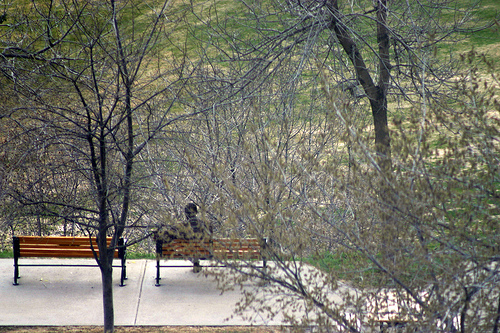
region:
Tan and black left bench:
[10, 229, 127, 279]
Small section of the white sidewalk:
[158, 290, 210, 320]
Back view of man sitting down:
[163, 202, 209, 239]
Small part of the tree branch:
[46, 198, 59, 208]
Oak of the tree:
[102, 302, 122, 322]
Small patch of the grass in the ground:
[236, 20, 242, 30]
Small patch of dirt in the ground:
[133, 327, 148, 332]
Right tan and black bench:
[158, 238, 272, 288]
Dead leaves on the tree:
[228, 310, 250, 324]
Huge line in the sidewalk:
[126, 259, 159, 324]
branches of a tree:
[420, 166, 455, 196]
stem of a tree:
[107, 291, 112, 306]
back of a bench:
[51, 220, 74, 250]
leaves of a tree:
[373, 213, 411, 262]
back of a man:
[181, 198, 193, 220]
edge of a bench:
[42, 223, 67, 256]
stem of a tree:
[385, 175, 425, 267]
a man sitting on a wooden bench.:
[127, 169, 304, 322]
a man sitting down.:
[176, 199, 220, 273]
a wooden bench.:
[0, 217, 144, 296]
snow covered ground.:
[0, 251, 499, 321]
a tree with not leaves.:
[63, 1, 126, 329]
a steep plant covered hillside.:
[3, 0, 498, 259]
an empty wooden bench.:
[0, 223, 137, 288]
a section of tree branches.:
[123, 59, 204, 146]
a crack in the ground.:
[131, 259, 154, 324]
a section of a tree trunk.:
[297, 50, 417, 127]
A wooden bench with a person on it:
[136, 187, 286, 289]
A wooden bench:
[2, 212, 144, 300]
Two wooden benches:
[8, 182, 293, 304]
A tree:
[250, 7, 461, 315]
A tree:
[15, 5, 204, 330]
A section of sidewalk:
[118, 289, 185, 325]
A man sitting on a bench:
[163, 186, 220, 281]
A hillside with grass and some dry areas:
[152, 5, 252, 63]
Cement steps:
[301, 255, 377, 330]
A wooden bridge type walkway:
[358, 269, 498, 331]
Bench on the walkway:
[7, 225, 139, 295]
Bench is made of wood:
[1, 228, 136, 297]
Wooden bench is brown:
[10, 230, 133, 287]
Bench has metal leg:
[6, 232, 29, 296]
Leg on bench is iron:
[5, 230, 32, 289]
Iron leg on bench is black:
[5, 230, 30, 291]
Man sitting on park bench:
[147, 185, 274, 289]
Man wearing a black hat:
[173, 191, 222, 221]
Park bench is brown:
[148, 232, 278, 289]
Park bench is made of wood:
[148, 230, 283, 296]